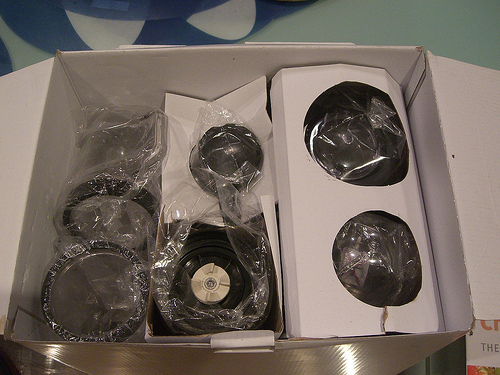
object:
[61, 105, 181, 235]
wrap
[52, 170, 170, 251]
container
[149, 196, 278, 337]
plastic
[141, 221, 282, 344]
blender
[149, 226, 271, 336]
ring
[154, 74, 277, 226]
cardboard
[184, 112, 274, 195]
pieces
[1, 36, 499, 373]
box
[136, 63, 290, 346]
middle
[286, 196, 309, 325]
paper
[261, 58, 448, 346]
cover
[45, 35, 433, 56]
edge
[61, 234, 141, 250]
edge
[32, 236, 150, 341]
wheel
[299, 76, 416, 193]
wrap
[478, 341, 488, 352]
letter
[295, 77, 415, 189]
opening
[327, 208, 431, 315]
bottom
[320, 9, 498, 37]
floor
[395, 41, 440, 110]
corner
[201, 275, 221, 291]
center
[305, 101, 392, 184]
parts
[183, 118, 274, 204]
cutout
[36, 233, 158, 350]
cup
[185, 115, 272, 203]
items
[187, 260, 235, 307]
bottom